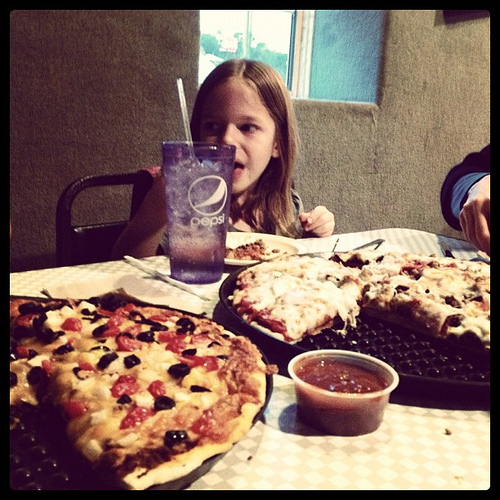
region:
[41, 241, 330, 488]
a pizza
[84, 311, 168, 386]
a pizza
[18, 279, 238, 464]
a pizza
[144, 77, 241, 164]
a straw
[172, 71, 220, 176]
a straw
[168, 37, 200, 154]
a straw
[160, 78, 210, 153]
a straw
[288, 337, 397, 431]
Dipping sauce in container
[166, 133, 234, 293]
Glass filled with soda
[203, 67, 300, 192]
Girl with blonde hair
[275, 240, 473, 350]
Cheese pizza pie on table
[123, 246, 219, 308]
Drinking straw on a table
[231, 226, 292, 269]
Slice of pizza on a plate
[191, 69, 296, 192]
Girl eating a slice of pizza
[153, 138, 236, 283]
Glass with pepsi logo on it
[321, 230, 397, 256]
Silver fork on a table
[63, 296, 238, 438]
Pizza pie with olives and tomatoes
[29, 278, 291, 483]
the pizza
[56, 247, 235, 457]
the pizza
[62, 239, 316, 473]
the pizza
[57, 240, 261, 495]
the pizza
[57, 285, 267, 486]
the pizza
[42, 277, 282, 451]
the pizza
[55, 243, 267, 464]
the pizza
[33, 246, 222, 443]
the pizza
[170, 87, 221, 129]
a straw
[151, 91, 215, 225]
a straw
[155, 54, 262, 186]
a straw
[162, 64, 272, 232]
a straw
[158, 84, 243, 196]
a straw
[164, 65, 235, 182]
a straw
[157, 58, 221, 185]
a straw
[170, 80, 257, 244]
a straw